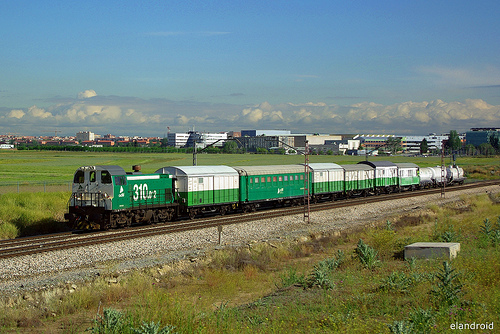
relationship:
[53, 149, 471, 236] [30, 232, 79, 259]
train on tracks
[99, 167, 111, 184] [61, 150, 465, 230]
window on train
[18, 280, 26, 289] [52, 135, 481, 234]
gravel along train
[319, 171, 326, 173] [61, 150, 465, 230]
paint on train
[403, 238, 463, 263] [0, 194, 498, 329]
stone in grass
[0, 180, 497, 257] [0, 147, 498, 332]
tracks on ground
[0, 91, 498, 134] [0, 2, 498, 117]
clouds in sky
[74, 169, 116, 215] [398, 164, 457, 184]
back of train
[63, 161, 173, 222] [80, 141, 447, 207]
train engine pulling cars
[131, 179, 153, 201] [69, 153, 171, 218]
310 on engine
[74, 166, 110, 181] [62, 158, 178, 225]
front windows of engine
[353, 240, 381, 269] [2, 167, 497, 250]
plants near tracks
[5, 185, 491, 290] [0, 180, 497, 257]
gravel along tracks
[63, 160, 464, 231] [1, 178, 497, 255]
train on railroad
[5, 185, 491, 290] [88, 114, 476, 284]
gravel beside railroad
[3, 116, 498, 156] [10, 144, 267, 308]
city behind railroad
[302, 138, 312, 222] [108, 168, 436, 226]
poles on train`s side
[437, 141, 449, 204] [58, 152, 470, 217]
poles beside train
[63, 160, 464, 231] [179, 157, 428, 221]
train hauling cars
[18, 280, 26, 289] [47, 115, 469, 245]
gravel alongside train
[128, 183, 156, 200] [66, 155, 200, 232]
numbers on train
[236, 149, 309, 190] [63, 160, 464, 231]
car of train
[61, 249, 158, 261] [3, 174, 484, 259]
rocks near tracks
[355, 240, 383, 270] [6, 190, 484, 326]
plants in field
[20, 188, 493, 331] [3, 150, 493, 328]
grass in field